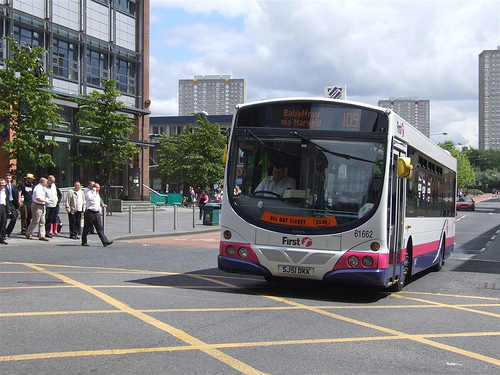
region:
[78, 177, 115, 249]
man in white shirt and black pants walking talking on his phone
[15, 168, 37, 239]
man wearing a cowboy hat standing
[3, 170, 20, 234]
man in black suit crossing the street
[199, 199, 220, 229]
green dumpster on sidewalk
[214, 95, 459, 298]
white pink and blue bus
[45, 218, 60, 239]
pink rain boots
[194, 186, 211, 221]
woman in red coat walking on the sidewalk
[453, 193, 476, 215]
red car on the street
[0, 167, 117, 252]
group of people crossing the street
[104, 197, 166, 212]
stairs going up the teh entrance of building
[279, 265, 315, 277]
the license plate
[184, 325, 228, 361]
yellow lines in the street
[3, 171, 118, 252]
people walking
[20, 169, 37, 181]
a man wearing a hat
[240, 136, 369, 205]
the windshield on the bus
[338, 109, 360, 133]
a number on the bus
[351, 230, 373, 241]
numbers on the bus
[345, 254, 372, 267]
headlights on the bus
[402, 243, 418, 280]
the front tire of the bus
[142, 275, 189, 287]
a shadow on the street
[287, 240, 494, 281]
pink and purple stripes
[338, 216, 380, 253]
black numbers on bus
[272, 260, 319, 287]
black and white license plate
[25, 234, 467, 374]
yellow crosswalk on street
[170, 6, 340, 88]
blue and white sky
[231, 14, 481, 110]
puffy white and grey clouds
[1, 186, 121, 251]
people walking on road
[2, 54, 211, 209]
trees in front of building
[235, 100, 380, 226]
windshield of the bus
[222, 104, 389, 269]
the bus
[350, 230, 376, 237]
numbers on the bus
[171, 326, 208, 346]
yellow lines in the street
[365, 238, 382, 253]
headlight on the bus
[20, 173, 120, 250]
people walking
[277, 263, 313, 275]
the license plate on the bus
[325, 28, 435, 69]
the clouds are white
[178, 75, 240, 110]
a tall building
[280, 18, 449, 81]
the clouds in the sky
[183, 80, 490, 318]
a large white bus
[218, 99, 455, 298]
a public transportation bus